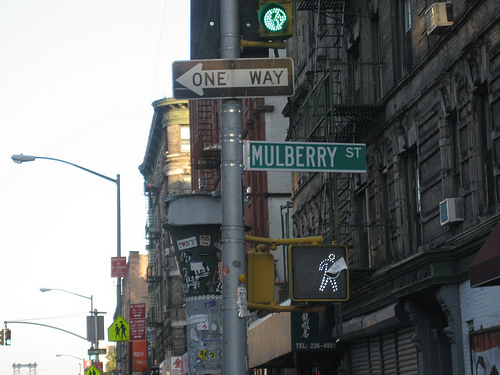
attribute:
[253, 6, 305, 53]
traffic light — green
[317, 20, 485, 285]
building — dark gray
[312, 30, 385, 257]
fire escape — black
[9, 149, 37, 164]
street light — extended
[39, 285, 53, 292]
street light — extended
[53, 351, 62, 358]
street light — extended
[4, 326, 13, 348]
traffic light — extended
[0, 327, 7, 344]
traffic light — extended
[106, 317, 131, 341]
sign — pedestrian, green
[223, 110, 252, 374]
pole — metal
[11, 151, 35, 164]
light — street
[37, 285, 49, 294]
light — street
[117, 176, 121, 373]
pole — tall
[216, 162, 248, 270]
pole — gray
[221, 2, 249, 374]
pole — metal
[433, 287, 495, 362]
paint — white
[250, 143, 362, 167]
letters — white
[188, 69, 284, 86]
letters — white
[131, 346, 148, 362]
letters — white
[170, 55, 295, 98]
sign — green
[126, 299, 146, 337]
sign — green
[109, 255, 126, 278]
sign — green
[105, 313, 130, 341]
sign — green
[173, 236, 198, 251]
stickers — many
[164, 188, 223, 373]
structure — funnel-shaped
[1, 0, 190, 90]
blue sky — bright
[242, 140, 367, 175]
sign — green, white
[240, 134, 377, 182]
sign — white , green 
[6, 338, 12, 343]
light — green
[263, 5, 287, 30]
light — green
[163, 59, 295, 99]
sign — white, black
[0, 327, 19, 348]
light — traffic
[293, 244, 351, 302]
light — on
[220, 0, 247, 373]
sign — black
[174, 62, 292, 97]
arrow — white